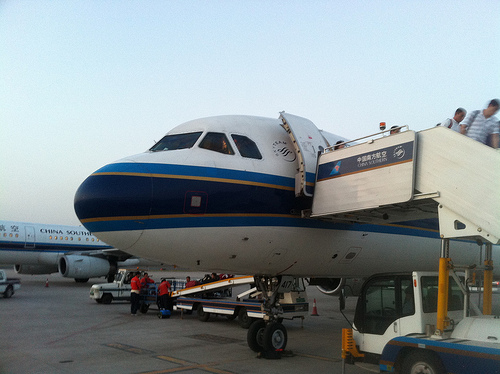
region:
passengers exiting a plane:
[325, 97, 499, 154]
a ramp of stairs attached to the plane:
[308, 123, 499, 249]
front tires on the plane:
[247, 273, 291, 357]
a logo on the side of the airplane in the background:
[37, 225, 91, 237]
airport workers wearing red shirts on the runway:
[126, 269, 228, 315]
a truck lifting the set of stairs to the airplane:
[339, 235, 499, 372]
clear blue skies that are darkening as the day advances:
[1, 0, 498, 229]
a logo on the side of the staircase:
[318, 142, 415, 178]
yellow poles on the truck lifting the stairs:
[431, 233, 496, 336]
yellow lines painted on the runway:
[101, 340, 353, 372]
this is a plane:
[70, 86, 497, 316]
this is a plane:
[2, 213, 133, 303]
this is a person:
[118, 256, 144, 319]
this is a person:
[145, 273, 176, 325]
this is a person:
[177, 266, 207, 316]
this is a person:
[132, 271, 156, 314]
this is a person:
[355, 109, 410, 173]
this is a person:
[422, 90, 472, 151]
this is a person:
[457, 88, 496, 168]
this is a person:
[121, 265, 158, 305]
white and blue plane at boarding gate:
[28, 81, 469, 290]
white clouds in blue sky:
[14, 20, 71, 68]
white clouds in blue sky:
[33, 75, 67, 112]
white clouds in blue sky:
[16, 122, 58, 163]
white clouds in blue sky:
[20, 168, 53, 208]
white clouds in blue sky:
[69, 30, 111, 79]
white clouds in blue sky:
[164, 20, 232, 70]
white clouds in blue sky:
[292, 25, 358, 75]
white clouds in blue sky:
[403, 13, 456, 62]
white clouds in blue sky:
[312, 69, 367, 111]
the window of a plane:
[198, 128, 234, 155]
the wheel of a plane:
[241, 316, 292, 357]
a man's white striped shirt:
[460, 106, 499, 141]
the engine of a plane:
[56, 250, 111, 282]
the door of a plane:
[25, 223, 37, 243]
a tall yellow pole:
[433, 255, 452, 330]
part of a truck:
[347, 273, 499, 372]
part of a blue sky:
[0, 0, 135, 63]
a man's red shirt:
[128, 274, 141, 291]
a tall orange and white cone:
[309, 291, 319, 315]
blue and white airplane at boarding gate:
[30, 83, 450, 363]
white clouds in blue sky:
[19, 105, 70, 152]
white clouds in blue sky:
[147, 10, 187, 62]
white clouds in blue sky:
[264, 36, 290, 71]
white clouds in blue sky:
[360, 39, 406, 86]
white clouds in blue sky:
[110, 21, 172, 88]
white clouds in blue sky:
[37, 101, 87, 141]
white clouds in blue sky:
[114, 43, 210, 98]